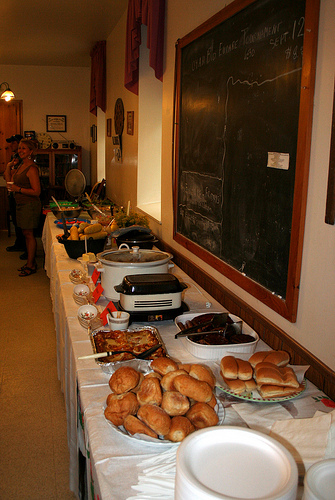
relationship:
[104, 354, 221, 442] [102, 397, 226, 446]
rolls on a plate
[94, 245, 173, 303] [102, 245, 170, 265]
crock pot has lid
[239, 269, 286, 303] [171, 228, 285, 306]
chalk on chalk holder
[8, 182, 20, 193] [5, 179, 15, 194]
hand holding cup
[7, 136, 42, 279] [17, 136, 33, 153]
person has hair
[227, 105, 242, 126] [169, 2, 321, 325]
part of a blackboard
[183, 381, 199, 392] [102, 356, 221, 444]
part of a bread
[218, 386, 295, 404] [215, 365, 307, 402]
edge of a plate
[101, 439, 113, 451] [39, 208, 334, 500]
part of cloth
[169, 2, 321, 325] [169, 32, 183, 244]
blackboard has edge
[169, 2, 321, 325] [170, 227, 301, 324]
blackboard has edge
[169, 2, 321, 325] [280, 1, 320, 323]
blackboard has edge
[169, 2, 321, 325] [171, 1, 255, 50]
blackboard has edge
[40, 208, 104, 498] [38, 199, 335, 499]
edge of a table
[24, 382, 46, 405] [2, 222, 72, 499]
part of floor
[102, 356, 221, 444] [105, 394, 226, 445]
bread on dish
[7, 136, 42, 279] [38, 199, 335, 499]
person close to table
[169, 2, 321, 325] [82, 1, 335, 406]
blackboard on wall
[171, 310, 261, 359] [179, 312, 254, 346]
container with meat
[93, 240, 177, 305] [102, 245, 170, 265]
pot has lid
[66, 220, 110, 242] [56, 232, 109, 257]
french bread in a bowl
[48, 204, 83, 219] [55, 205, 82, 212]
bowl of food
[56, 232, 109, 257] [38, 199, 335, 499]
bowl on table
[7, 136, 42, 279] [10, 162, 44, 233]
person wearing a dress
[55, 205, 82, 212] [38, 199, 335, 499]
food on a table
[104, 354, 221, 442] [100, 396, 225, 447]
rolls in a bowl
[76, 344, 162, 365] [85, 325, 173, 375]
serving spoon in tray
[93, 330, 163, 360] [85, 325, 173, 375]
food in tray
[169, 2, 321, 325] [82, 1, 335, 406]
blackboard hanging on wall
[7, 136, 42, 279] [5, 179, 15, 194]
person holding cup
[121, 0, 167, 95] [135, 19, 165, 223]
curtains on window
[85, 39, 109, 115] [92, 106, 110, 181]
curtains on window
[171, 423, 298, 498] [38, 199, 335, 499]
plates are on table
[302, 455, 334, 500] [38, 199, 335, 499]
plates are on table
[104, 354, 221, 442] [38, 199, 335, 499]
rolls are on table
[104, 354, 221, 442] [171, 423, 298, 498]
rolls are next to plates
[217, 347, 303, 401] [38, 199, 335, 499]
rolls are on table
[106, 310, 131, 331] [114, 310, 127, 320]
cup with food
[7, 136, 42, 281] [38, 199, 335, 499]
person next to table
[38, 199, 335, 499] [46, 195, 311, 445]
table with food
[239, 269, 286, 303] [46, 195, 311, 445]
chalk next to food